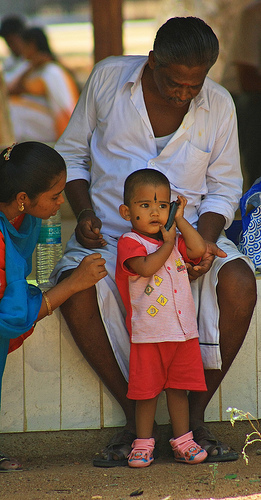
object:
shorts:
[126, 337, 208, 402]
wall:
[0, 277, 261, 454]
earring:
[18, 202, 25, 215]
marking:
[136, 213, 141, 222]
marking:
[154, 192, 158, 202]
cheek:
[133, 209, 141, 225]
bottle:
[36, 208, 63, 287]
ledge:
[23, 268, 259, 300]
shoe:
[168, 430, 208, 465]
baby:
[115, 168, 207, 470]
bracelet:
[42, 289, 51, 317]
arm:
[2, 274, 79, 337]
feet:
[167, 428, 209, 464]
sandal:
[92, 416, 161, 467]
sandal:
[171, 426, 240, 462]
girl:
[1, 140, 108, 402]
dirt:
[93, 464, 209, 498]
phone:
[164, 199, 179, 231]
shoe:
[127, 435, 155, 467]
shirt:
[54, 53, 243, 236]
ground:
[1, 449, 261, 500]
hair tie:
[2, 144, 14, 160]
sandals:
[126, 437, 157, 470]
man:
[52, 14, 257, 467]